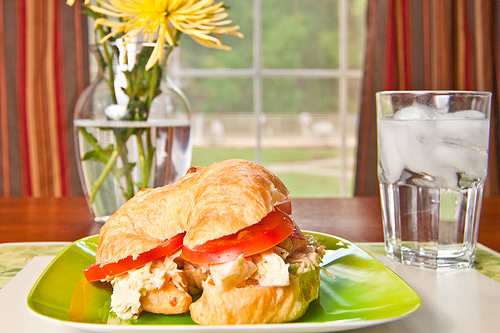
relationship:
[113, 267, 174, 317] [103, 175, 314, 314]
chicken on sandwich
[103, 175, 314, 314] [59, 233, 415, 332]
sandwich on plate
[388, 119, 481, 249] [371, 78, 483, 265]
water in glass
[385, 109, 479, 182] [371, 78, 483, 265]
ice cubes in glass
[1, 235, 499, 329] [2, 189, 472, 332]
placemat on table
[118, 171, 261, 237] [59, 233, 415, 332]
croissant on plate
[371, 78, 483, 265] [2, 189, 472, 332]
glass on table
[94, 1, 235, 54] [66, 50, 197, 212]
flowers in vase